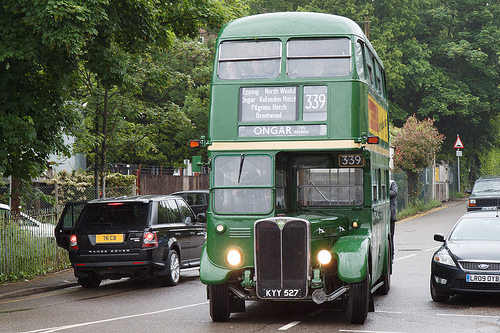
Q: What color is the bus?
A: Green.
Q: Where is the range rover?
A: To the left of the bus.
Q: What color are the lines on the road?
A: White.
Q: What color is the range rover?
A: Black.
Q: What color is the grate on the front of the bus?
A: Black.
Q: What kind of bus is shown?
A: Double decker.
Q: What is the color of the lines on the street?
A: White.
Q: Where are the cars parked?
A: Beside the sidewalk.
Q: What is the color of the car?
A: Black.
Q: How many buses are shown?
A: One.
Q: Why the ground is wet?
A: It was raining.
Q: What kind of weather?
A: Overcast.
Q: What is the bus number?
A: 339.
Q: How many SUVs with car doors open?
A: One.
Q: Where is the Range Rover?
A: On the far left.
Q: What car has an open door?
A: The black SUV.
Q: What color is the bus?
A: Green and yellow.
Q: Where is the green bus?
A: In the middle of the street.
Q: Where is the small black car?
A: On the right.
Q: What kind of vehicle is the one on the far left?
A: A range rover.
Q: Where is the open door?
A: On the black SUV.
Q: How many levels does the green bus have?
A: Two.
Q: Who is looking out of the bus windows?
A: Passengers.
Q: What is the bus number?
A: 339.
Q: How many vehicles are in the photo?
A: 5.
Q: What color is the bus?
A: Green.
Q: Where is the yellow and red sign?
A: On the side of the bus.